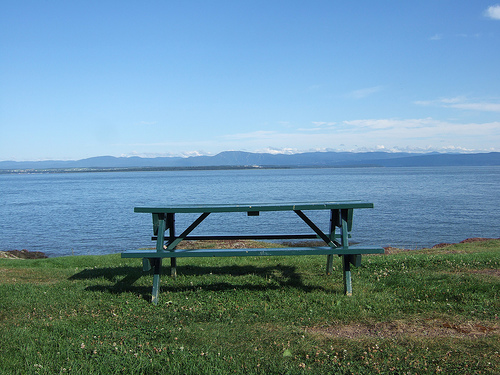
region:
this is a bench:
[125, 192, 382, 311]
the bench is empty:
[126, 192, 377, 309]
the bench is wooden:
[126, 193, 372, 308]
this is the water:
[417, 170, 467, 222]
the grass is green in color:
[215, 300, 286, 360]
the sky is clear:
[106, 8, 361, 102]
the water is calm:
[395, 167, 482, 218]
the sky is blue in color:
[89, 10, 332, 97]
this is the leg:
[335, 267, 357, 298]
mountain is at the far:
[211, 147, 251, 163]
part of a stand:
[140, 260, 162, 306]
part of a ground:
[223, 298, 258, 345]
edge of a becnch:
[177, 225, 206, 266]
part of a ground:
[257, 275, 295, 345]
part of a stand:
[338, 263, 367, 296]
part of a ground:
[386, 292, 427, 347]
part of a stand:
[140, 256, 186, 311]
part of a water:
[409, 178, 447, 214]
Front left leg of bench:
[135, 212, 176, 304]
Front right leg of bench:
[335, 208, 360, 298]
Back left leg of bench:
[164, 212, 181, 279]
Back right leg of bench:
[324, 209, 339, 276]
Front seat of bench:
[107, 244, 390, 263]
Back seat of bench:
[143, 229, 353, 244]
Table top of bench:
[123, 194, 380, 223]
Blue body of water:
[0, 163, 499, 254]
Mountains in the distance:
[0, 143, 499, 172]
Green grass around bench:
[0, 244, 499, 374]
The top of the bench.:
[138, 198, 375, 213]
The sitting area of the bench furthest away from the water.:
[128, 240, 385, 261]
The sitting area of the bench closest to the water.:
[149, 225, 354, 239]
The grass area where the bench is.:
[17, 258, 498, 366]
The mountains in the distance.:
[15, 146, 491, 159]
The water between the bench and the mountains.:
[11, 160, 495, 247]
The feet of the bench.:
[125, 250, 357, 290]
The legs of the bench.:
[145, 213, 357, 289]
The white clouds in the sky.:
[277, 31, 491, 144]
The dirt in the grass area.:
[310, 314, 499, 339]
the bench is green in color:
[130, 188, 365, 313]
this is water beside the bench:
[381, 164, 463, 232]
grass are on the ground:
[213, 279, 327, 319]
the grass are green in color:
[221, 283, 309, 315]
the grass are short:
[183, 323, 281, 370]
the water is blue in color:
[376, 180, 460, 223]